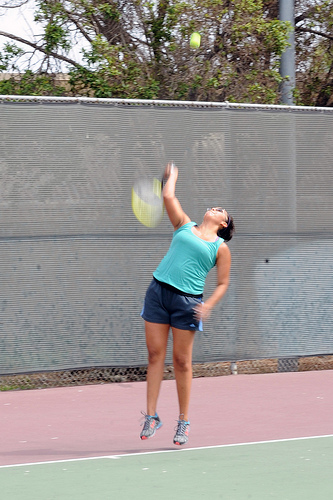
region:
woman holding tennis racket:
[87, 170, 243, 435]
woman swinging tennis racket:
[100, 161, 246, 453]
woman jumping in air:
[94, 159, 261, 475]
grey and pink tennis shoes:
[142, 413, 184, 445]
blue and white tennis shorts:
[137, 284, 211, 330]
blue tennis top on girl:
[153, 228, 228, 290]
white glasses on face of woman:
[206, 203, 225, 214]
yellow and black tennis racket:
[126, 166, 175, 230]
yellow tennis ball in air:
[187, 33, 208, 55]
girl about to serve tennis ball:
[103, 17, 253, 400]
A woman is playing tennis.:
[112, 150, 246, 459]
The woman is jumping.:
[114, 149, 237, 465]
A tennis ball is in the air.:
[171, 29, 211, 52]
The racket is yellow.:
[119, 155, 176, 231]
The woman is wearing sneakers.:
[135, 404, 195, 443]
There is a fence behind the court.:
[8, 91, 330, 380]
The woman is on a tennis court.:
[5, 384, 323, 497]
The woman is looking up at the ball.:
[120, 148, 239, 470]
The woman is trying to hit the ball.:
[116, 154, 246, 469]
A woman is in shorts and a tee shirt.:
[117, 151, 243, 452]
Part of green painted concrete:
[5, 475, 32, 497]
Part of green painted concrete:
[37, 461, 69, 490]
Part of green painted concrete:
[68, 478, 91, 497]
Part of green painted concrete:
[88, 459, 141, 484]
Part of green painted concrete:
[118, 480, 135, 491]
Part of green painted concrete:
[137, 447, 163, 479]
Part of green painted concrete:
[159, 475, 201, 498]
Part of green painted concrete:
[202, 454, 246, 474]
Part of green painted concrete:
[210, 477, 259, 498]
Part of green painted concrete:
[270, 446, 323, 493]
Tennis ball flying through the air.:
[182, 29, 205, 51]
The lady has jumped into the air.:
[126, 160, 244, 452]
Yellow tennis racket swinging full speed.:
[123, 156, 181, 230]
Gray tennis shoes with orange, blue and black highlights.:
[132, 407, 199, 448]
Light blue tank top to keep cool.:
[150, 218, 230, 297]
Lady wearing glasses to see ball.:
[201, 203, 238, 238]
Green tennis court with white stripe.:
[3, 436, 331, 496]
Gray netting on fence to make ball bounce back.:
[4, 89, 332, 370]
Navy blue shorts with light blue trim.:
[130, 275, 217, 334]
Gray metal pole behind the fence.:
[271, 3, 308, 371]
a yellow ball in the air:
[183, 30, 203, 50]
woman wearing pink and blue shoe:
[137, 412, 161, 440]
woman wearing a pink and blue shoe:
[169, 418, 190, 443]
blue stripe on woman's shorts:
[194, 293, 208, 332]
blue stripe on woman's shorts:
[139, 275, 152, 320]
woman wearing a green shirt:
[151, 217, 221, 299]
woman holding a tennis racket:
[125, 160, 178, 228]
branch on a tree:
[42, 2, 128, 70]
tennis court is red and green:
[0, 368, 332, 498]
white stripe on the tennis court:
[0, 432, 331, 465]